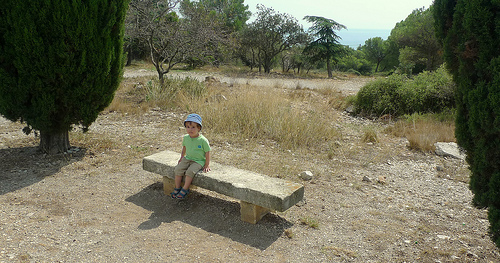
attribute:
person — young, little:
[172, 113, 216, 205]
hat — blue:
[185, 114, 205, 126]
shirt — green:
[178, 133, 210, 170]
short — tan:
[177, 157, 204, 176]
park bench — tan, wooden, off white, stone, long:
[140, 146, 304, 227]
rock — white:
[301, 167, 316, 182]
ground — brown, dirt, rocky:
[0, 55, 500, 262]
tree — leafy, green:
[306, 12, 347, 81]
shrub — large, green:
[2, 2, 136, 166]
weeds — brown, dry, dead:
[122, 75, 374, 153]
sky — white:
[237, 0, 434, 29]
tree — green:
[227, 0, 308, 79]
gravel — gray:
[318, 132, 479, 251]